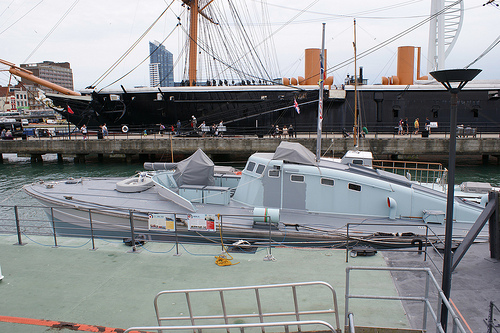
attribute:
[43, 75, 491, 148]
ship — black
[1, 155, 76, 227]
water — still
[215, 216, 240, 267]
rope — yellow 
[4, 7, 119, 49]
sky — gray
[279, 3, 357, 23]
sky — gray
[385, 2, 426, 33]
sky — gray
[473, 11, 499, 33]
sky — gray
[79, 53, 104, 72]
sky — gray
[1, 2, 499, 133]
ship — large, black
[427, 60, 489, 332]
light post — tall, black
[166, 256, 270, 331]
railings — white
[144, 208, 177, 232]
sign — small, white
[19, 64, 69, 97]
building — tall, grey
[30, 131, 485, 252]
boat — white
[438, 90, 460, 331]
post — black 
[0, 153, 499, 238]
water — calm